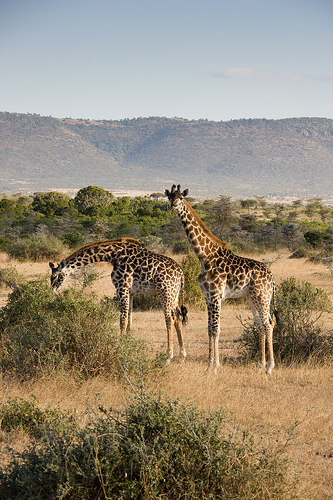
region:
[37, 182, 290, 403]
two giraffes in African prarie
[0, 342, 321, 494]
shrub atop African prarie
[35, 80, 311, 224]
African mountain range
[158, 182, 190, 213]
head of giraffe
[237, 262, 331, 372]
shrub atop African prarie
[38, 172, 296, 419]
African wildlife scene featuring two giraffes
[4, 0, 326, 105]
mostly clear sky with a single cloud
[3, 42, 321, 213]
moutains and sky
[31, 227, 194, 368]
giraffe eating foilage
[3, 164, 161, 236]
row of trees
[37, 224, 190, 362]
Giraffe eating the grass.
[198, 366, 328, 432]
Brown grass in the forefront.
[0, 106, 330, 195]
Mountains in the background.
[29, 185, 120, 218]
Trees in the background.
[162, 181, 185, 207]
Two horns on the top of the giraffe's head.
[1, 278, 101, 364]
Green bush in the forefront.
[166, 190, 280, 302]
Brown spots on the giraffe.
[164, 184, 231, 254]
Brown mane on the giraffe.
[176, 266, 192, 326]
Black hair on the end of the giraffe's tail.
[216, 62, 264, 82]
White cloud in the sky.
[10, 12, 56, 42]
white clouds in blue sky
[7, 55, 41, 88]
white clouds in blue sky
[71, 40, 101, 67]
white clouds in blue sky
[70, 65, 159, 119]
white clouds in blue sky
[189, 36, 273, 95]
white clouds in blue sky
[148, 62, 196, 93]
white clouds in blue sky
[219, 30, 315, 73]
white clouds in blue sky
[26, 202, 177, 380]
brown spotted giraffe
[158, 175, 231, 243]
brown spotted giraffe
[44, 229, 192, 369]
giraffe eating a bush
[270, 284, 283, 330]
tail of the giraffe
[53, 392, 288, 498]
green bush on the ground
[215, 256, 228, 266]
brown and white spots on the giraffe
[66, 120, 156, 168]
bushy hills in the background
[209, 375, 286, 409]
tan grass on the ground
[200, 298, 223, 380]
front legs of the giraffe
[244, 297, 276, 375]
back legs of the giraffe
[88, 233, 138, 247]
brown mane of the giraffe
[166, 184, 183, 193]
horns on top of the giraffe's head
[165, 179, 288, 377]
a giraffe on the savannah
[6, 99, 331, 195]
hills on the horizon line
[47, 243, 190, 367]
a giraffe eats leaves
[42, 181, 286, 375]
two giraffes stand on the savannah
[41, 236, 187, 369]
a giraffe feeds from a large bush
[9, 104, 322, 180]
rolling hills meet the hazy sky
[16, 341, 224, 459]
dry grass and short bushes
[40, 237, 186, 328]
a giraffe bends to eat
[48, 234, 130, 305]
a giraffe eats leaves from the bushes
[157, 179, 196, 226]
the giraffe turns toward the camers